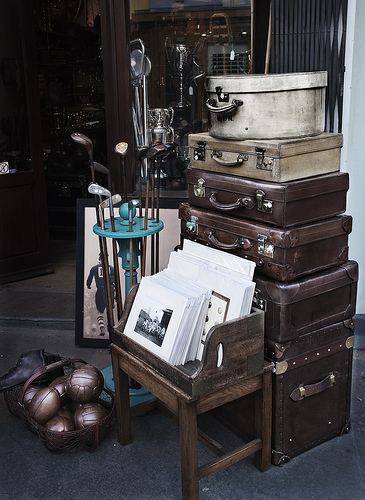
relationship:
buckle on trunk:
[214, 157, 246, 173] [240, 137, 333, 177]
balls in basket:
[27, 373, 93, 420] [45, 434, 103, 454]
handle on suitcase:
[194, 193, 263, 212] [264, 190, 345, 220]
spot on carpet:
[197, 483, 209, 495] [94, 462, 156, 478]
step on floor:
[0, 306, 71, 327] [46, 279, 69, 293]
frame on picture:
[213, 288, 236, 302] [64, 208, 110, 339]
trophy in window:
[143, 96, 177, 163] [124, 0, 250, 63]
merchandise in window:
[125, 23, 200, 137] [124, 0, 250, 63]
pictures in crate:
[123, 288, 195, 346] [144, 351, 226, 396]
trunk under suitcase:
[240, 137, 333, 177] [264, 190, 345, 220]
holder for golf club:
[78, 195, 149, 285] [54, 124, 116, 225]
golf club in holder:
[54, 124, 116, 225] [78, 195, 149, 285]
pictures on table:
[123, 288, 195, 346] [145, 187, 190, 199]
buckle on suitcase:
[214, 157, 246, 173] [264, 190, 345, 220]